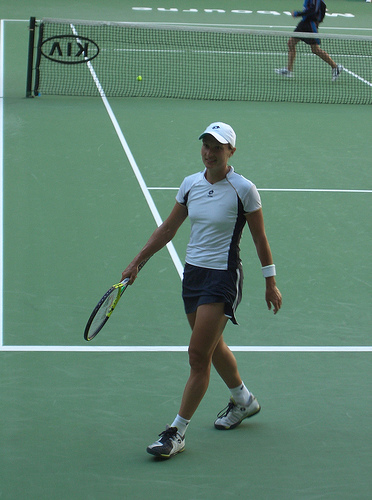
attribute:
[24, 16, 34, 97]
pole — black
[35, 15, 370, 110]
net — black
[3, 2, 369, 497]
floor — green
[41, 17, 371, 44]
border — white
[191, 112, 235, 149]
cap — white 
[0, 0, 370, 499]
tennis court — in use